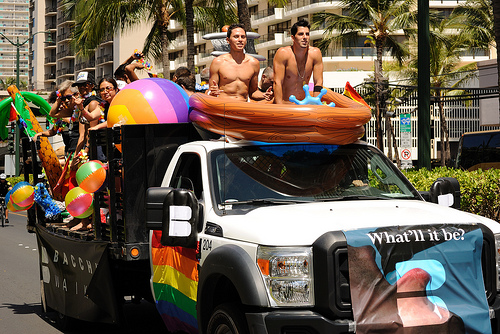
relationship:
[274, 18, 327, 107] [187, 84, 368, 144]
guy in boat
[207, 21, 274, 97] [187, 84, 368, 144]
guy in boat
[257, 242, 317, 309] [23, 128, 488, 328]
headlight on truck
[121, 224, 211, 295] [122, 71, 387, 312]
flag on truck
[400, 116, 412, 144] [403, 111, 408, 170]
sign on pole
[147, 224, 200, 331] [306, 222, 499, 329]
flag on front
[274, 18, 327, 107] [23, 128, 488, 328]
guy on truck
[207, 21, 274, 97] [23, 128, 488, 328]
guy on truck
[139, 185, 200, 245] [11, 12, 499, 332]
mirror on truck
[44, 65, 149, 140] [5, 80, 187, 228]
people with beach toys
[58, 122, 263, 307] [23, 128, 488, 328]
sign on truck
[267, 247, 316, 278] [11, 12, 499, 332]
headlight on truck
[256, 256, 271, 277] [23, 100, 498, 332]
turn signal on truck